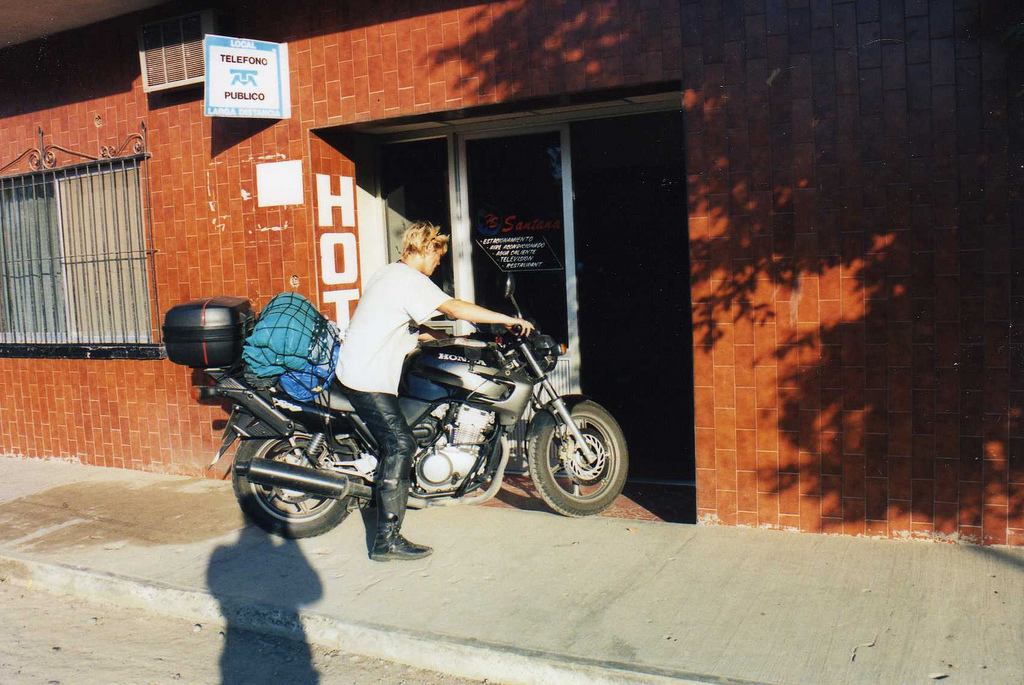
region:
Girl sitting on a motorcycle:
[220, 216, 601, 545]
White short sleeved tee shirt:
[337, 237, 449, 399]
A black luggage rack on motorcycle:
[160, 281, 250, 371]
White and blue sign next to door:
[193, 34, 288, 134]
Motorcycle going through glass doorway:
[351, 132, 668, 515]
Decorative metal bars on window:
[9, 137, 186, 365]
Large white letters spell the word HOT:
[291, 140, 378, 312]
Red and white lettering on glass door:
[470, 170, 568, 313]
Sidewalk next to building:
[31, 446, 551, 682]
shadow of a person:
[206, 478, 346, 681]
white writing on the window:
[473, 226, 553, 281]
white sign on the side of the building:
[236, 147, 303, 214]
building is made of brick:
[0, 3, 1023, 545]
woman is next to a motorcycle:
[200, 190, 621, 568]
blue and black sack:
[250, 279, 342, 412]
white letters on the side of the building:
[314, 171, 371, 327]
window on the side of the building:
[4, 133, 182, 378]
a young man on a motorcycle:
[327, 224, 537, 561]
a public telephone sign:
[203, 35, 293, 121]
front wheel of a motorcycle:
[526, 395, 632, 517]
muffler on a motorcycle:
[231, 455, 372, 504]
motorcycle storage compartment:
[153, 294, 249, 367]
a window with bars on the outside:
[0, 119, 166, 354]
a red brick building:
[1, 0, 1022, 545]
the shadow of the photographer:
[206, 490, 327, 683]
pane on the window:
[118, 151, 153, 254]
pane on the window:
[99, 243, 138, 341]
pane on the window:
[23, 200, 25, 262]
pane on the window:
[93, 165, 144, 186]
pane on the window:
[112, 331, 132, 352]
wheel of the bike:
[535, 392, 619, 525]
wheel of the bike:
[203, 459, 337, 545]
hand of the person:
[514, 304, 553, 350]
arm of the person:
[419, 296, 515, 328]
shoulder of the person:
[364, 263, 431, 298]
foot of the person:
[361, 538, 415, 558]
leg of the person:
[362, 427, 408, 522]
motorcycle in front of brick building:
[158, 219, 624, 537]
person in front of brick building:
[158, 223, 629, 559]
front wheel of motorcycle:
[524, 397, 626, 515]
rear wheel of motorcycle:
[228, 436, 357, 539]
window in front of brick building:
[51, 159, 155, 344]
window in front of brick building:
[0, 179, 65, 338]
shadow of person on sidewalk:
[206, 491, 331, 682]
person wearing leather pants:
[333, 224, 532, 557]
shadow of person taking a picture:
[205, 490, 326, 683]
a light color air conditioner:
[123, 19, 221, 92]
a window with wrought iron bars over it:
[0, 143, 169, 365]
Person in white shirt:
[247, 203, 491, 539]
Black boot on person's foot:
[359, 503, 442, 564]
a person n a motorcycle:
[165, 216, 647, 568]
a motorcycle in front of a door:
[157, 283, 636, 543]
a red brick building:
[10, 11, 1006, 550]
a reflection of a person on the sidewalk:
[204, 475, 325, 682]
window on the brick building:
[4, 151, 172, 371]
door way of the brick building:
[295, 82, 720, 542]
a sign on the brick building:
[184, 17, 302, 136]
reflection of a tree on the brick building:
[424, 11, 1023, 575]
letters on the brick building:
[307, 157, 369, 345]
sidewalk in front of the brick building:
[8, 444, 1018, 683]